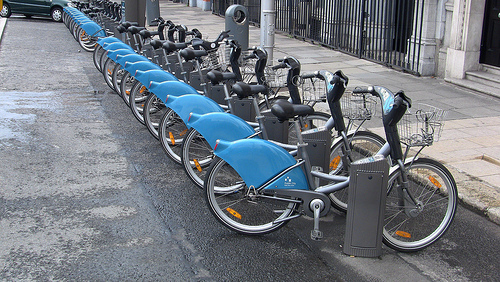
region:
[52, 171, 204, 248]
this is the road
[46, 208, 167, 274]
the road is grey in color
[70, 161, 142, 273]
the road is clean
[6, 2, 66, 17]
this is a car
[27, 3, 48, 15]
the car is green in color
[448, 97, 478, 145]
this is a pavement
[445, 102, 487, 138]
the pavement is clean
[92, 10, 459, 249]
these are some bicycles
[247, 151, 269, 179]
the part is blue in color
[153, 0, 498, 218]
The sidewalk near the street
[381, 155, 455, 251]
The front tire of the bicycle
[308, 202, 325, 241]
A pedal on the bicycle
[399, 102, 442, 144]
A basket on the bicycle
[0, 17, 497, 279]
The street below the bicycles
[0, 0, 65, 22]
A car parked near the bicycles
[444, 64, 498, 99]
Steps by the building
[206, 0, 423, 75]
A fence by the building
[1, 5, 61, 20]
Wheels on the car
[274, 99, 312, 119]
The seat of the bicycle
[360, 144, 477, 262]
wheel of a bike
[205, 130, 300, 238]
wheel of a bike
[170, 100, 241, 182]
wheel of a bike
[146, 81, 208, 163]
wheel of a bike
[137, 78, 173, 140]
wheel of a bike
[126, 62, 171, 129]
wheel of a bike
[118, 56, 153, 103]
wheel of a bike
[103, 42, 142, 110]
wheel of a bike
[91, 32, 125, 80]
wheel of a bike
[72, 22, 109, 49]
wheel of a bike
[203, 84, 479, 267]
This is a bike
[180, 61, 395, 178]
This is a bike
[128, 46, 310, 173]
This is a bike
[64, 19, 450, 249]
these are bicycles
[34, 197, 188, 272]
this is the road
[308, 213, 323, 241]
this is the pedal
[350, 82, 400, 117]
these are the handles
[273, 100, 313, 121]
this is the bicycle seat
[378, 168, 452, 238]
this is the front wheel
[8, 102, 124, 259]
the road is tarmacked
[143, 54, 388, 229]
the bicycles are metalic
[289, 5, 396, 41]
the grills are metallic